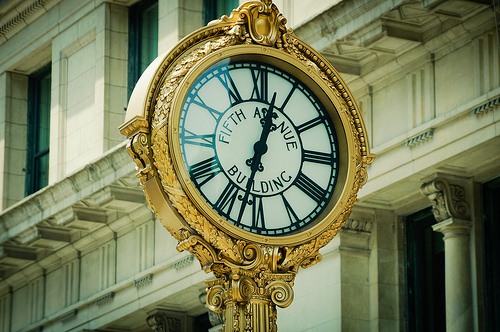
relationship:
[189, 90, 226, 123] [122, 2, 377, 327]
numeral on clock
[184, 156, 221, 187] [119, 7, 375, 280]
roman numeral on clock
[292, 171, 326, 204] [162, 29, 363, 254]
numeral in clock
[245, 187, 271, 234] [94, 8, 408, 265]
numeral on clock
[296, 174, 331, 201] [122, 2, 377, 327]
numeral on clock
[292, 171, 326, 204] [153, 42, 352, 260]
numeral on clock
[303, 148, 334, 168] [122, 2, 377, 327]
roman numeral on clock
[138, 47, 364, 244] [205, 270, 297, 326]
clock on pole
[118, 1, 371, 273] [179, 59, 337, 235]
golden frame around clock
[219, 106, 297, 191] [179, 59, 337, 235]
writing on clock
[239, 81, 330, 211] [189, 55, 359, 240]
hand of clock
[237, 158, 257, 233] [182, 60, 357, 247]
hand of clock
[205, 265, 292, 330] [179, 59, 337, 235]
pole on bottom of clock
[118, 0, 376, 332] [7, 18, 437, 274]
clock in front of building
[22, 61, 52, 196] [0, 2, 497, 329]
window on top of building